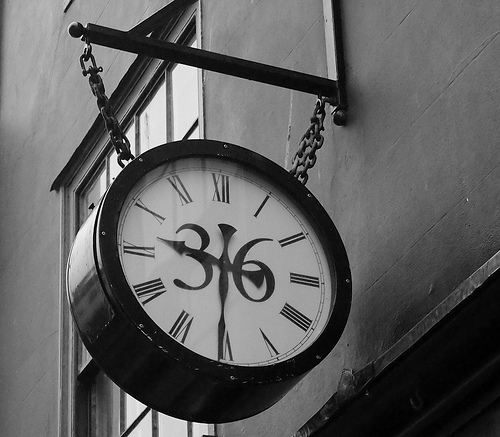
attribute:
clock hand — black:
[157, 238, 264, 289]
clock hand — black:
[217, 223, 237, 358]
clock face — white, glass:
[114, 154, 334, 367]